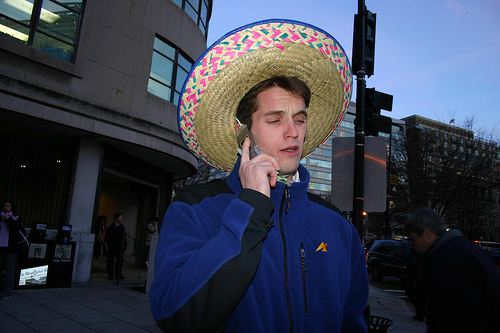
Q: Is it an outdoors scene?
A: Yes, it is outdoors.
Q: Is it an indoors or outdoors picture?
A: It is outdoors.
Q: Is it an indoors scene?
A: No, it is outdoors.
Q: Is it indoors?
A: No, it is outdoors.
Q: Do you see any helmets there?
A: No, there are no helmets.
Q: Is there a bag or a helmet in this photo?
A: No, there are no helmets or bags.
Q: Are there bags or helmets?
A: No, there are no helmets or bags.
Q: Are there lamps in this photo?
A: No, there are no lamps.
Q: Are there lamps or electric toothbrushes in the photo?
A: No, there are no lamps or electric toothbrushes.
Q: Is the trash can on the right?
A: Yes, the trash can is on the right of the image.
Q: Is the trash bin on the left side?
A: No, the trash bin is on the right of the image.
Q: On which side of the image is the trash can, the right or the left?
A: The trash can is on the right of the image.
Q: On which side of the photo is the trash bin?
A: The trash bin is on the right of the image.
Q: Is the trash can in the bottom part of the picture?
A: Yes, the trash can is in the bottom of the image.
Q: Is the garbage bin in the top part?
A: No, the garbage bin is in the bottom of the image.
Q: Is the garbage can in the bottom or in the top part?
A: The garbage can is in the bottom of the image.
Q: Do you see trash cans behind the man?
A: Yes, there is a trash can behind the man.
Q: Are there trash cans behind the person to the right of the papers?
A: Yes, there is a trash can behind the man.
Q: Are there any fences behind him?
A: No, there is a trash can behind the man.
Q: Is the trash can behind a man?
A: Yes, the trash can is behind a man.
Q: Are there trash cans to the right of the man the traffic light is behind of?
A: Yes, there is a trash can to the right of the man.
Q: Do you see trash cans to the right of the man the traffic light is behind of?
A: Yes, there is a trash can to the right of the man.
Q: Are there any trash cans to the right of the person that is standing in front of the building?
A: Yes, there is a trash can to the right of the man.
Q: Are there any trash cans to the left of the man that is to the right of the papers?
A: No, the trash can is to the right of the man.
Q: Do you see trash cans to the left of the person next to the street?
A: No, the trash can is to the right of the man.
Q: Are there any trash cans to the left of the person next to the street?
A: No, the trash can is to the right of the man.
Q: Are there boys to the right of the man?
A: No, there is a trash can to the right of the man.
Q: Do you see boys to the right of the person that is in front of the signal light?
A: No, there is a trash can to the right of the man.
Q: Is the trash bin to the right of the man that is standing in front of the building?
A: Yes, the trash bin is to the right of the man.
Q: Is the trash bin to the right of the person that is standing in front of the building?
A: Yes, the trash bin is to the right of the man.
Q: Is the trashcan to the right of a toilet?
A: No, the trashcan is to the right of the man.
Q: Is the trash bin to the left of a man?
A: No, the trash bin is to the right of a man.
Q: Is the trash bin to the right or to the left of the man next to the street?
A: The trash bin is to the right of the man.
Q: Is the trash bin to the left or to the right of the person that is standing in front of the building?
A: The trash bin is to the right of the man.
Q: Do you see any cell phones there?
A: Yes, there is a cell phone.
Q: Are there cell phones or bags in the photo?
A: Yes, there is a cell phone.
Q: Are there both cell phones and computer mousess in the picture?
A: No, there is a cell phone but no computer mousess.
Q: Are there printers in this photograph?
A: No, there are no printers.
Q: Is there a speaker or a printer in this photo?
A: No, there are no printers or speakers.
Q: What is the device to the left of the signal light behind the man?
A: The device is a cell phone.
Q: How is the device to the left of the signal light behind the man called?
A: The device is a cell phone.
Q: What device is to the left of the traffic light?
A: The device is a cell phone.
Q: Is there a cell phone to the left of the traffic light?
A: Yes, there is a cell phone to the left of the traffic light.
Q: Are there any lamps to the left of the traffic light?
A: No, there is a cell phone to the left of the traffic light.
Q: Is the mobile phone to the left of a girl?
A: No, the mobile phone is to the left of a traffic light.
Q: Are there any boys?
A: No, there are no boys.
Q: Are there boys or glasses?
A: No, there are no boys or glasses.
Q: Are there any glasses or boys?
A: No, there are no boys or glasses.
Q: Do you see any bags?
A: No, there are no bags.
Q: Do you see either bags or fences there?
A: No, there are no bags or fences.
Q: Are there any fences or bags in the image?
A: No, there are no bags or fences.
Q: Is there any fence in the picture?
A: No, there are no fences.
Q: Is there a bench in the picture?
A: No, there are no benches.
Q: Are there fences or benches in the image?
A: No, there are no benches or fences.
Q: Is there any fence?
A: No, there are no fences.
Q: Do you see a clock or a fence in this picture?
A: No, there are no fences or clocks.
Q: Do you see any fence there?
A: No, there are no fences.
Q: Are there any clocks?
A: No, there are no clocks.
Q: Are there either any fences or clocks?
A: No, there are no clocks or fences.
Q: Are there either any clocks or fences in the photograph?
A: No, there are no clocks or fences.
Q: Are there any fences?
A: No, there are no fences.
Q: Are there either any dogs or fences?
A: No, there are no fences or dogs.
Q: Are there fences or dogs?
A: No, there are no fences or dogs.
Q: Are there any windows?
A: Yes, there is a window.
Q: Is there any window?
A: Yes, there is a window.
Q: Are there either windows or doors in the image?
A: Yes, there is a window.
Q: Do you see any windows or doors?
A: Yes, there is a window.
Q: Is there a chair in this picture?
A: No, there are no chairs.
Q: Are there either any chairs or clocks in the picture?
A: No, there are no chairs or clocks.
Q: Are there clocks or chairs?
A: No, there are no chairs or clocks.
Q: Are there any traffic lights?
A: Yes, there is a traffic light.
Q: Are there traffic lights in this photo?
A: Yes, there is a traffic light.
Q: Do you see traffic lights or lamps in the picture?
A: Yes, there is a traffic light.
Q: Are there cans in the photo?
A: No, there are no cans.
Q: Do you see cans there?
A: No, there are no cans.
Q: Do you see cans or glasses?
A: No, there are no cans or glasses.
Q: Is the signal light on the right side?
A: Yes, the signal light is on the right of the image.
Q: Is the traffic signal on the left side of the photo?
A: No, the traffic signal is on the right of the image.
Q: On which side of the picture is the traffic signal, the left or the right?
A: The traffic signal is on the right of the image.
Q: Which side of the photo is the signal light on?
A: The signal light is on the right of the image.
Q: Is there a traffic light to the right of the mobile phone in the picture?
A: Yes, there is a traffic light to the right of the mobile phone.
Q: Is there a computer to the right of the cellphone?
A: No, there is a traffic light to the right of the cellphone.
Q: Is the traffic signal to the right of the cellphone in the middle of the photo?
A: Yes, the traffic signal is to the right of the mobile phone.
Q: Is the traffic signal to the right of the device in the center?
A: Yes, the traffic signal is to the right of the mobile phone.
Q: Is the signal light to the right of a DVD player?
A: No, the signal light is to the right of the mobile phone.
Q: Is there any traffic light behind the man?
A: Yes, there is a traffic light behind the man.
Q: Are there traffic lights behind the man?
A: Yes, there is a traffic light behind the man.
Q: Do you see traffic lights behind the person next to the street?
A: Yes, there is a traffic light behind the man.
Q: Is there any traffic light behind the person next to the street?
A: Yes, there is a traffic light behind the man.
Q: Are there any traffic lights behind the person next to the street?
A: Yes, there is a traffic light behind the man.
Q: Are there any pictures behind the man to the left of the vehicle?
A: No, there is a traffic light behind the man.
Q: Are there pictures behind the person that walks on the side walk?
A: No, there is a traffic light behind the man.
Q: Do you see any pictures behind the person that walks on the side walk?
A: No, there is a traffic light behind the man.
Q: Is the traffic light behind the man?
A: Yes, the traffic light is behind the man.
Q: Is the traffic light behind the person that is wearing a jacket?
A: Yes, the traffic light is behind the man.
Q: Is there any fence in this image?
A: No, there are no fences.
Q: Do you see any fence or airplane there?
A: No, there are no fences or airplanes.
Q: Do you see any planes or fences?
A: No, there are no fences or planes.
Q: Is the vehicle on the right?
A: Yes, the vehicle is on the right of the image.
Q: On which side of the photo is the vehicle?
A: The vehicle is on the right of the image.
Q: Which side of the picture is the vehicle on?
A: The vehicle is on the right of the image.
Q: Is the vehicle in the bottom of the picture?
A: Yes, the vehicle is in the bottom of the image.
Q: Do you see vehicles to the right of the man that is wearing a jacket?
A: Yes, there is a vehicle to the right of the man.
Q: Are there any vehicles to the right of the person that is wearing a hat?
A: Yes, there is a vehicle to the right of the man.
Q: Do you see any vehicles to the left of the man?
A: No, the vehicle is to the right of the man.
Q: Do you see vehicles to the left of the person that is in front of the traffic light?
A: No, the vehicle is to the right of the man.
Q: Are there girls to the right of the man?
A: No, there is a vehicle to the right of the man.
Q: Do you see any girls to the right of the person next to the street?
A: No, there is a vehicle to the right of the man.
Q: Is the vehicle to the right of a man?
A: Yes, the vehicle is to the right of a man.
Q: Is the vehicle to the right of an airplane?
A: No, the vehicle is to the right of a man.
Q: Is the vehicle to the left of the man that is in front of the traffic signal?
A: No, the vehicle is to the right of the man.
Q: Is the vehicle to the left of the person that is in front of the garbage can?
A: No, the vehicle is to the right of the man.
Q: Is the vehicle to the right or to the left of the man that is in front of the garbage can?
A: The vehicle is to the right of the man.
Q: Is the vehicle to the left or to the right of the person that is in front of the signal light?
A: The vehicle is to the right of the man.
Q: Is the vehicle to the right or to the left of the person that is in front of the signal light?
A: The vehicle is to the right of the man.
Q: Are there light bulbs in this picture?
A: No, there are no light bulbs.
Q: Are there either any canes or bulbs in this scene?
A: No, there are no bulbs or canes.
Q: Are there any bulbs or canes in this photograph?
A: No, there are no bulbs or canes.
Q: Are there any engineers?
A: No, there are no engineers.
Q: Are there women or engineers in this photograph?
A: No, there are no engineers or women.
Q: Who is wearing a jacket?
A: The man is wearing a jacket.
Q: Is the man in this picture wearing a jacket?
A: Yes, the man is wearing a jacket.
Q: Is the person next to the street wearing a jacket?
A: Yes, the man is wearing a jacket.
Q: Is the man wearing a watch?
A: No, the man is wearing a jacket.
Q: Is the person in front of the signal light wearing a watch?
A: No, the man is wearing a jacket.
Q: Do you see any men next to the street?
A: Yes, there is a man next to the street.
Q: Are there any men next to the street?
A: Yes, there is a man next to the street.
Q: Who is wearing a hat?
A: The man is wearing a hat.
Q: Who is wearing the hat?
A: The man is wearing a hat.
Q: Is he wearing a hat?
A: Yes, the man is wearing a hat.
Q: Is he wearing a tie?
A: No, the man is wearing a hat.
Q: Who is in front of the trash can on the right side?
A: The man is in front of the trash can.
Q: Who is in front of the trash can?
A: The man is in front of the trash can.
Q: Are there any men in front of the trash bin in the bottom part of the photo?
A: Yes, there is a man in front of the trash can.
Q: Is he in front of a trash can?
A: Yes, the man is in front of a trash can.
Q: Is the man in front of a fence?
A: No, the man is in front of a trash can.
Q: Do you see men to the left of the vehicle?
A: Yes, there is a man to the left of the vehicle.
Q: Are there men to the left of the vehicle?
A: Yes, there is a man to the left of the vehicle.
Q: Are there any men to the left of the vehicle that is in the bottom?
A: Yes, there is a man to the left of the vehicle.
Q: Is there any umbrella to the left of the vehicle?
A: No, there is a man to the left of the vehicle.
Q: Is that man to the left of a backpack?
A: No, the man is to the left of the vehicle.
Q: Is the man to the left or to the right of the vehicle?
A: The man is to the left of the vehicle.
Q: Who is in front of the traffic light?
A: The man is in front of the traffic light.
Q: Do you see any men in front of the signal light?
A: Yes, there is a man in front of the signal light.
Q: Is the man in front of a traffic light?
A: Yes, the man is in front of a traffic light.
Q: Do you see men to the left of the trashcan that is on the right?
A: Yes, there is a man to the left of the garbage can.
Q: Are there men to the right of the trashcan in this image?
A: No, the man is to the left of the trashcan.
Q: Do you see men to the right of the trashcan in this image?
A: No, the man is to the left of the trashcan.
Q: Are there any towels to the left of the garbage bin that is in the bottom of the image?
A: No, there is a man to the left of the trash can.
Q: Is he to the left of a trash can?
A: Yes, the man is to the left of a trash can.